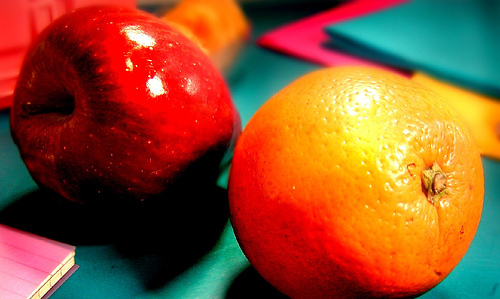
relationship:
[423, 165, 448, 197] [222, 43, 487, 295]
stem on orange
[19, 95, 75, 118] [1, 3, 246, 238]
stem on apple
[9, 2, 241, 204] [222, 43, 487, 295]
apple together with orange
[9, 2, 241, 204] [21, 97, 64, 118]
apple has stem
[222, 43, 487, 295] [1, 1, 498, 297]
orange on a table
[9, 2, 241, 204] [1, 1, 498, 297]
apple on table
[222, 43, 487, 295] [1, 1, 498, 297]
orange on table